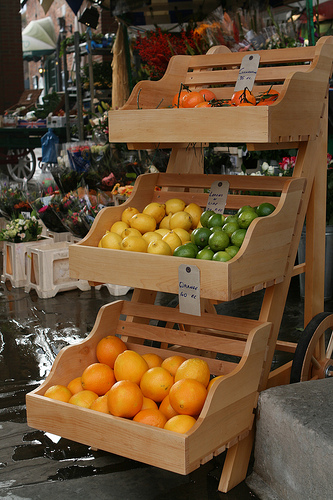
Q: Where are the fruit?
A: Wooden cart.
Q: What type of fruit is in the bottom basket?
A: Oranges.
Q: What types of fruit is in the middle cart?
A: Lemons and limes.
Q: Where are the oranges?
A: On the stand.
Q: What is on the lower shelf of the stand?
A: Oranges.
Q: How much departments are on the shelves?
A: Three.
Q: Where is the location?
A: The market.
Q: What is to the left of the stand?
A: Display of flowers.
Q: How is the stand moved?
A: It has a wheel.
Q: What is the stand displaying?
A: Fruits.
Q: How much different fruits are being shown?
A: Four.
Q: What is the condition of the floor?
A: It is wet.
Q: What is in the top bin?
A: Tangerines.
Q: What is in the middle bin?
A: Lemons and limes.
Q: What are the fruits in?
A: A wooden bin with shelves.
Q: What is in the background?
A: Flowers.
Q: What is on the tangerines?
A: Stems and leaves.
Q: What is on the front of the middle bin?
A: A price tag.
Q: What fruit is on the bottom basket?
A: Orange.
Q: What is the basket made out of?
A: Wood.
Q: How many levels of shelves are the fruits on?
A: 3.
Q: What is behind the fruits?
A: Flowers.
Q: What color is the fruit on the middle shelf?
A: Green and yellow.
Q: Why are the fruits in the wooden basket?
A: For storage.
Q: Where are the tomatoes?
A: Top Basket.